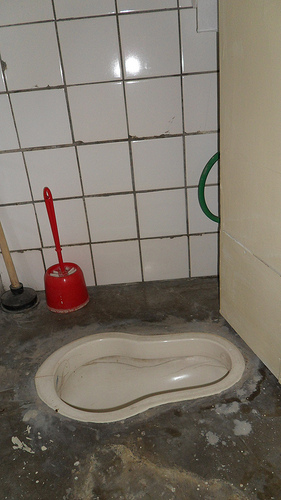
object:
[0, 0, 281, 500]
toilet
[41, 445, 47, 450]
spots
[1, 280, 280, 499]
floor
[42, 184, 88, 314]
toilet brush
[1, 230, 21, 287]
handle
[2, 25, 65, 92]
tiles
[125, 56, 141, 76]
light reflection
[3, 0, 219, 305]
wall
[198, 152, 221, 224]
hose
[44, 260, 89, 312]
container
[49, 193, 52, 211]
plastic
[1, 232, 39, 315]
plunger